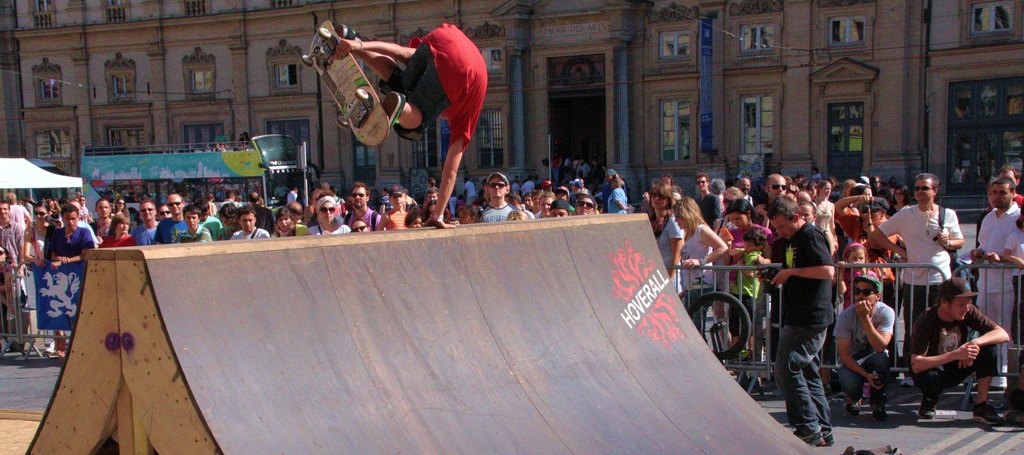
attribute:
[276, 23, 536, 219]
person — skateboarding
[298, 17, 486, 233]
shirt — red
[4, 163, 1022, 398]
crowd — large